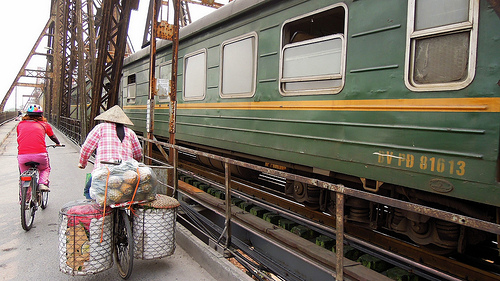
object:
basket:
[58, 202, 116, 273]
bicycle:
[80, 159, 134, 280]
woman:
[15, 102, 61, 205]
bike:
[19, 143, 65, 231]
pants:
[17, 151, 54, 199]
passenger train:
[69, 0, 500, 258]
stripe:
[121, 96, 500, 112]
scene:
[0, 0, 500, 280]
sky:
[0, 0, 228, 113]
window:
[277, 3, 351, 95]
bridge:
[0, 0, 500, 280]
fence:
[56, 116, 500, 281]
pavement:
[0, 113, 208, 281]